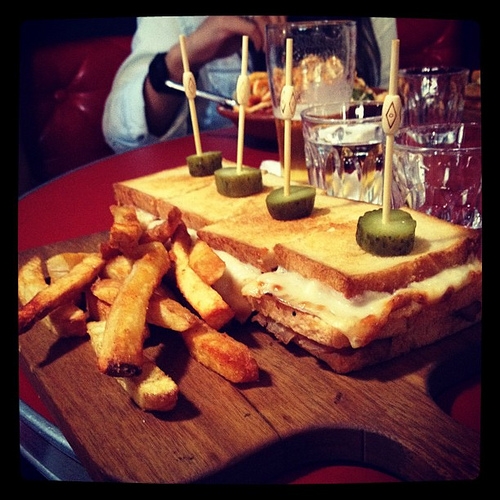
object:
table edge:
[19, 402, 94, 492]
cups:
[299, 100, 400, 204]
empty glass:
[392, 117, 480, 231]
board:
[16, 226, 483, 486]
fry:
[104, 201, 140, 252]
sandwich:
[109, 148, 297, 249]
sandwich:
[195, 186, 389, 319]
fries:
[22, 245, 97, 335]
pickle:
[216, 165, 263, 198]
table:
[14, 126, 500, 485]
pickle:
[265, 187, 316, 221]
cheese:
[256, 258, 471, 345]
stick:
[277, 35, 302, 190]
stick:
[233, 35, 258, 167]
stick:
[178, 33, 208, 152]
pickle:
[356, 205, 418, 256]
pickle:
[183, 148, 224, 176]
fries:
[168, 236, 237, 334]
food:
[236, 55, 373, 111]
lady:
[103, 4, 460, 163]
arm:
[102, 14, 189, 156]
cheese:
[209, 247, 264, 283]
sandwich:
[251, 204, 487, 378]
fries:
[186, 240, 258, 317]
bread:
[280, 202, 478, 297]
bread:
[109, 153, 297, 231]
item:
[148, 50, 175, 97]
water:
[314, 143, 381, 182]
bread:
[197, 189, 379, 265]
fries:
[184, 316, 261, 386]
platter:
[14, 173, 484, 487]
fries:
[95, 247, 168, 373]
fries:
[82, 320, 184, 413]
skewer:
[378, 40, 401, 226]